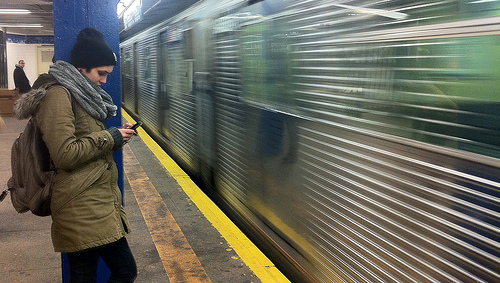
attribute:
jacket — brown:
[19, 69, 132, 256]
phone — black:
[124, 116, 143, 136]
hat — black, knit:
[70, 27, 116, 65]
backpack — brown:
[11, 120, 53, 220]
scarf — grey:
[50, 61, 117, 119]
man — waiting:
[14, 60, 32, 97]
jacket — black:
[14, 66, 33, 91]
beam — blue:
[54, 1, 124, 283]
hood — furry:
[15, 74, 61, 115]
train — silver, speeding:
[114, 0, 500, 282]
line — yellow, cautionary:
[122, 109, 299, 282]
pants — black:
[68, 239, 139, 283]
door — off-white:
[39, 46, 59, 79]